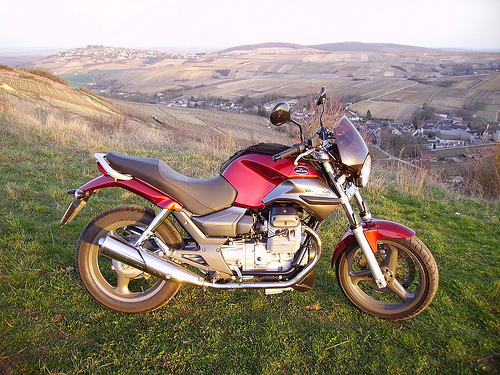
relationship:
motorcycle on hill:
[58, 84, 439, 325] [6, 135, 499, 373]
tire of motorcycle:
[337, 236, 441, 323] [58, 84, 440, 322]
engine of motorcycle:
[210, 202, 307, 279] [58, 84, 439, 325]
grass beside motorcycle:
[235, 307, 363, 358] [58, 84, 440, 322]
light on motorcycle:
[338, 146, 403, 198] [58, 84, 439, 325]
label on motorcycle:
[292, 166, 309, 175] [58, 84, 440, 322]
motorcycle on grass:
[58, 84, 439, 325] [1, 35, 496, 368]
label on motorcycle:
[292, 162, 310, 173] [61, 58, 453, 339]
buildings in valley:
[390, 78, 468, 166] [101, 90, 494, 195]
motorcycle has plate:
[58, 84, 439, 325] [59, 199, 83, 225]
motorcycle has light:
[58, 84, 440, 322] [360, 153, 372, 187]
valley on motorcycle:
[0, 40, 500, 372] [58, 84, 440, 322]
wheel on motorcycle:
[75, 204, 189, 316] [58, 84, 440, 322]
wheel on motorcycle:
[337, 235, 438, 319] [58, 84, 440, 322]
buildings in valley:
[410, 114, 487, 179] [0, 40, 500, 372]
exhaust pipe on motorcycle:
[99, 221, 322, 290] [58, 84, 440, 322]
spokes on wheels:
[365, 265, 399, 286] [328, 229, 453, 326]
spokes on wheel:
[365, 265, 399, 286] [337, 235, 438, 319]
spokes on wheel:
[94, 227, 164, 296] [75, 204, 189, 316]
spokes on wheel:
[365, 265, 399, 286] [75, 204, 189, 316]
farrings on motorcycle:
[330, 115, 371, 167] [58, 84, 440, 322]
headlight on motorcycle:
[354, 149, 377, 189] [58, 84, 440, 322]